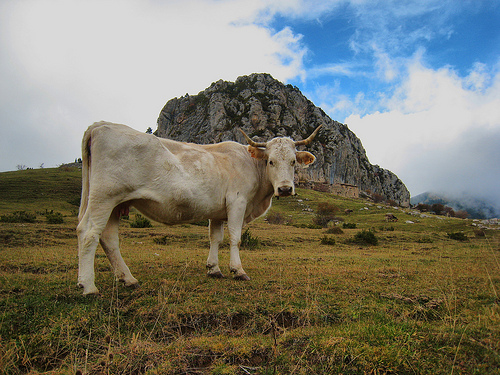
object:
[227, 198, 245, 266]
legs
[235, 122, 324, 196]
head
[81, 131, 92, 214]
tail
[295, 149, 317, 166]
ears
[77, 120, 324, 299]
bull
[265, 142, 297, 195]
face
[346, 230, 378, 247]
shrub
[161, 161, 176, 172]
white tan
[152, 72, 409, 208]
hill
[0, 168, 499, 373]
field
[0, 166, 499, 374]
grass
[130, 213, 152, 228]
bush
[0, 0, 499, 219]
cloud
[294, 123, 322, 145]
horns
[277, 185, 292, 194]
nose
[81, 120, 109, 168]
hind end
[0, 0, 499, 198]
sky